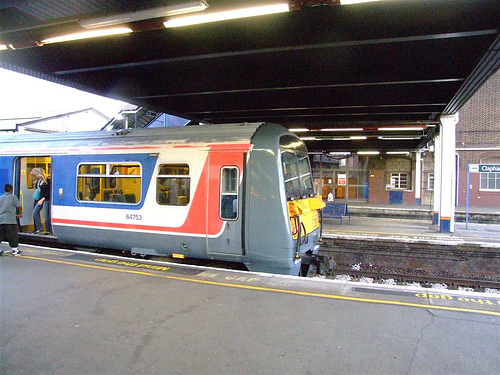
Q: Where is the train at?
A: Train station.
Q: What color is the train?
A: Gray.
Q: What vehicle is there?
A: Train.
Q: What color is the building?
A: Brown.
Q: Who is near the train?
A: Man.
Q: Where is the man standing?
A: Near train.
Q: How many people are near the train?
A: One.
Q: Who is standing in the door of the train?
A: Lady.